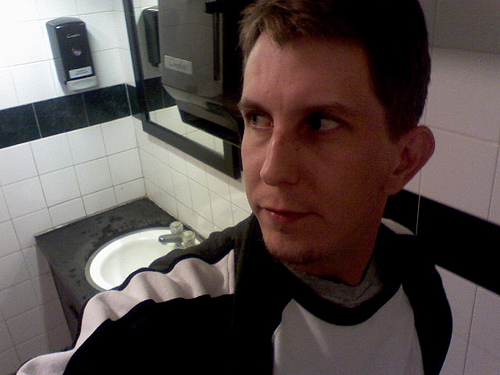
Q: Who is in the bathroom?
A: The man.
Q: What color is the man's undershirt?
A: Grey.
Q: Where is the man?
A: In the bathroom.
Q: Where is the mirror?
A: On the wall.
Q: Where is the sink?
A: On the counter.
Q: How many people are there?
A: One.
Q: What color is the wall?
A: White and black.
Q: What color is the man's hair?
A: Brown.